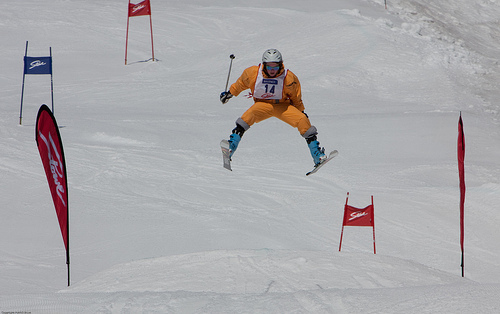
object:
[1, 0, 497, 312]
snow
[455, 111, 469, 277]
flag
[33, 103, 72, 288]
flag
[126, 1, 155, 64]
flag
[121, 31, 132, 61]
sticks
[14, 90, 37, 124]
sticks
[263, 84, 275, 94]
14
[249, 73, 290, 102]
chest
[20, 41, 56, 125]
banner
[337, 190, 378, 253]
banner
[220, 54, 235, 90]
guide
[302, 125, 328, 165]
boots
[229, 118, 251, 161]
boots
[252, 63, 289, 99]
bib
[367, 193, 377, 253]
stick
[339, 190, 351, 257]
stick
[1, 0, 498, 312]
snow hill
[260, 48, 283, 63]
helmet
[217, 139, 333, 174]
snowboarder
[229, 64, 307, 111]
ski suit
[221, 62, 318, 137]
snowsuit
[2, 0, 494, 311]
ground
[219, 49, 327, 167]
him